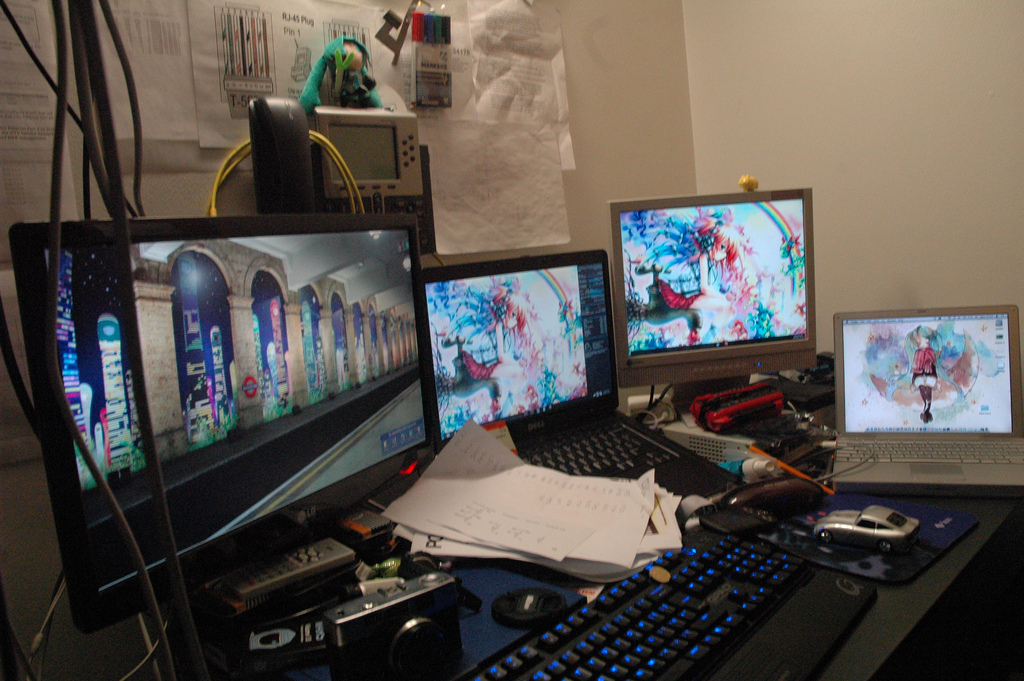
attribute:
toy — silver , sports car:
[813, 502, 926, 552]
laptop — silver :
[829, 303, 1020, 491]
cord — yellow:
[195, 122, 368, 216]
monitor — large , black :
[6, 197, 467, 638]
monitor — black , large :
[20, 209, 442, 614]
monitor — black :
[421, 253, 622, 465]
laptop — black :
[410, 229, 745, 519]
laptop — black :
[415, 244, 740, 506]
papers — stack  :
[391, 428, 683, 576]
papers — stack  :
[378, 408, 705, 571]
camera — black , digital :
[318, 549, 466, 668]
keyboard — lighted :
[443, 534, 802, 675]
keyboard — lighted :
[439, 514, 803, 659]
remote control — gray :
[223, 534, 353, 617]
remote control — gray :
[220, 529, 363, 622]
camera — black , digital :
[311, 559, 474, 666]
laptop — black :
[432, 229, 735, 506]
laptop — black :
[402, 201, 740, 564]